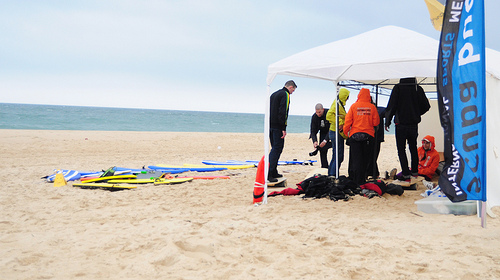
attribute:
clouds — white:
[29, 49, 154, 106]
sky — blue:
[19, 13, 264, 137]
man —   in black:
[248, 87, 316, 172]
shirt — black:
[266, 88, 291, 136]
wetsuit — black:
[307, 108, 329, 170]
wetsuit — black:
[266, 74, 298, 195]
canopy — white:
[264, 20, 444, 95]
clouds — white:
[75, 40, 98, 74]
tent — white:
[305, 22, 406, 78]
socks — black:
[307, 148, 319, 158]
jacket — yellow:
[328, 96, 346, 133]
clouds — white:
[56, 70, 122, 94]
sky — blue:
[0, 7, 270, 68]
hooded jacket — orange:
[343, 86, 382, 137]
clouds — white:
[23, 14, 300, 72]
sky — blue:
[5, 4, 440, 114]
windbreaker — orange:
[342, 87, 377, 143]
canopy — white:
[262, 23, 498, 213]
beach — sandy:
[1, 126, 498, 277]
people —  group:
[241, 70, 428, 195]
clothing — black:
[390, 78, 427, 181]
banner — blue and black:
[432, 2, 488, 206]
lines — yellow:
[282, 89, 293, 125]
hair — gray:
[310, 97, 328, 121]